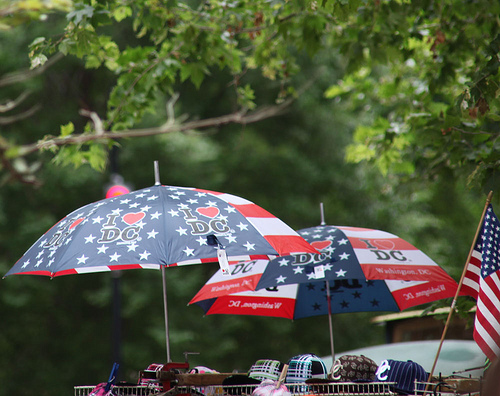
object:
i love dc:
[357, 236, 407, 263]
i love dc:
[181, 200, 231, 236]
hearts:
[193, 203, 226, 223]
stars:
[180, 244, 199, 259]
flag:
[452, 200, 500, 372]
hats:
[350, 358, 427, 393]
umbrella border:
[187, 273, 461, 321]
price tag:
[216, 247, 233, 278]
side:
[166, 231, 284, 274]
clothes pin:
[275, 362, 290, 389]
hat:
[248, 380, 292, 395]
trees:
[0, 0, 263, 192]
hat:
[282, 351, 327, 391]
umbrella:
[186, 201, 471, 363]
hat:
[304, 353, 379, 386]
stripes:
[464, 325, 500, 363]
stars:
[489, 264, 497, 271]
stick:
[421, 186, 495, 383]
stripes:
[350, 246, 457, 268]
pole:
[160, 263, 172, 366]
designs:
[348, 361, 367, 380]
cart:
[73, 365, 499, 395]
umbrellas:
[3, 158, 325, 367]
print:
[353, 361, 364, 380]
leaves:
[355, 121, 418, 172]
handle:
[422, 297, 456, 387]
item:
[1, 185, 321, 283]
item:
[186, 226, 471, 325]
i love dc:
[97, 210, 149, 244]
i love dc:
[41, 214, 87, 253]